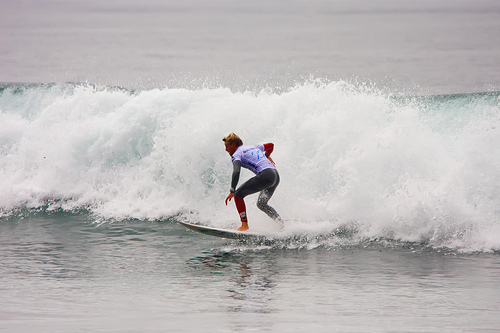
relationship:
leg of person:
[234, 170, 277, 224] [221, 128, 286, 232]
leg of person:
[230, 170, 270, 230] [220, 131, 280, 231]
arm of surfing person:
[227, 157, 242, 197] [220, 131, 280, 231]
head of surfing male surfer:
[222, 130, 242, 153] [178, 131, 286, 239]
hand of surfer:
[223, 192, 234, 203] [221, 131, 288, 236]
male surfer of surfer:
[178, 131, 286, 239] [217, 132, 283, 227]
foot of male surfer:
[236, 220, 250, 235] [178, 131, 286, 239]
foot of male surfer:
[271, 217, 288, 230] [178, 131, 286, 239]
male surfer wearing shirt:
[178, 131, 286, 239] [233, 143, 276, 174]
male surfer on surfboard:
[178, 131, 286, 239] [175, 211, 358, 251]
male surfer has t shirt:
[178, 131, 286, 239] [231, 144, 277, 175]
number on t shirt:
[239, 142, 259, 154] [231, 144, 277, 175]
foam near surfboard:
[4, 83, 495, 256] [167, 211, 344, 241]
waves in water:
[195, 240, 351, 273] [21, 30, 476, 322]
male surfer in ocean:
[218, 132, 288, 231] [0, 1, 498, 330]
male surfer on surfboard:
[178, 131, 286, 239] [177, 220, 279, 244]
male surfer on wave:
[178, 131, 286, 239] [4, 77, 496, 251]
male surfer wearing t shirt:
[178, 131, 286, 239] [228, 144, 276, 176]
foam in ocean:
[4, 83, 495, 256] [0, 1, 498, 330]